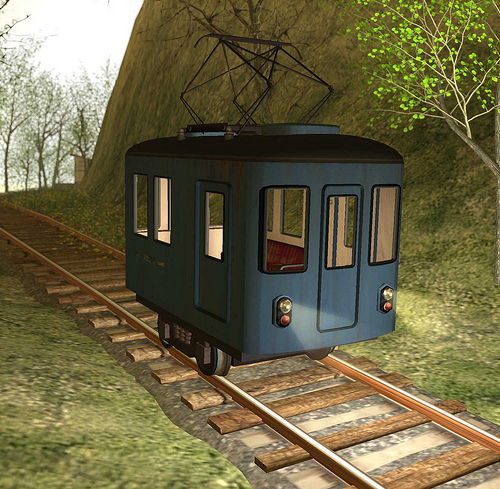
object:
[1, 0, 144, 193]
sky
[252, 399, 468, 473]
slat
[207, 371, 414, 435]
slat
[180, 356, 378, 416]
slat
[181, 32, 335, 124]
structure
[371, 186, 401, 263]
window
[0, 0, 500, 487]
photo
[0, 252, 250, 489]
grass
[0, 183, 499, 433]
track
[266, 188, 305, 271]
window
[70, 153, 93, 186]
building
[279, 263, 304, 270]
railing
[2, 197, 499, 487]
railway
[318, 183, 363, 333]
door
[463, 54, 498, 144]
branch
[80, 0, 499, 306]
wall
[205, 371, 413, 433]
bar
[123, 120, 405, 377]
car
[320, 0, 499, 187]
tree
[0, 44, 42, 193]
tree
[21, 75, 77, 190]
tree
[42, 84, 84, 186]
tree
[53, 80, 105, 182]
tree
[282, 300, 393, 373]
light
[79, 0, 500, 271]
hill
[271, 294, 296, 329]
headlights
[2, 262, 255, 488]
tracks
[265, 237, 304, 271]
seat